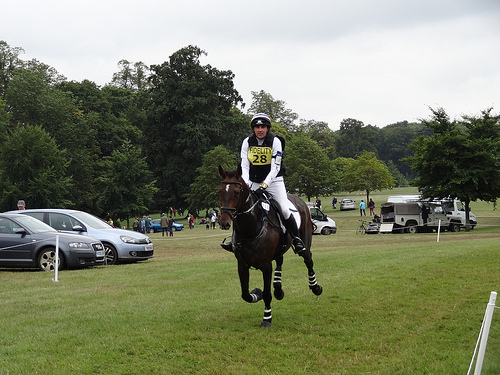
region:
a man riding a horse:
[197, 92, 342, 330]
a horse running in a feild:
[172, 178, 319, 315]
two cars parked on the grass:
[0, 211, 167, 283]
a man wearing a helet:
[214, 102, 302, 194]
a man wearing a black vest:
[232, 91, 287, 204]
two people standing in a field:
[353, 193, 378, 214]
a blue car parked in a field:
[148, 209, 182, 243]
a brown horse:
[186, 161, 342, 323]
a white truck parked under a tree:
[361, 107, 494, 277]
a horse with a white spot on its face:
[207, 160, 246, 246]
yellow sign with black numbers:
[244, 137, 286, 174]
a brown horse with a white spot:
[212, 168, 300, 293]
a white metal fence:
[6, 232, 71, 279]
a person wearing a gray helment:
[249, 110, 279, 141]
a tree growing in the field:
[423, 112, 498, 249]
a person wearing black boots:
[285, 189, 320, 283]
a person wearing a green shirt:
[356, 188, 368, 221]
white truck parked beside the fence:
[380, 194, 471, 255]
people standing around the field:
[134, 203, 194, 248]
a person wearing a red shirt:
[169, 202, 180, 220]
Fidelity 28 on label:
[235, 137, 290, 175]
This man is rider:
[172, 93, 344, 341]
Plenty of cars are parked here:
[11, 167, 478, 284]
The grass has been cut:
[42, 203, 490, 360]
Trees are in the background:
[8, 26, 418, 200]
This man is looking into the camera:
[232, 99, 323, 263]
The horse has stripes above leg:
[192, 205, 357, 345]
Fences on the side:
[36, 220, 491, 344]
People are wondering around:
[299, 163, 410, 238]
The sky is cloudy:
[135, 9, 433, 147]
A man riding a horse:
[207, 110, 342, 321]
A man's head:
[231, 112, 282, 139]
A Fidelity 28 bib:
[244, 141, 280, 169]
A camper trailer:
[363, 183, 480, 244]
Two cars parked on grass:
[2, 193, 163, 282]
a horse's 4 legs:
[227, 260, 340, 336]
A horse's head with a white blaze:
[191, 159, 253, 236]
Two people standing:
[356, 194, 377, 220]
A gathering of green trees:
[16, 44, 180, 174]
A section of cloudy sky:
[299, 12, 424, 99]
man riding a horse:
[217, 112, 326, 334]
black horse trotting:
[216, 179, 331, 336]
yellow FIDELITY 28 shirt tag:
[247, 144, 275, 166]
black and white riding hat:
[247, 110, 269, 127]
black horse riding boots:
[282, 211, 307, 254]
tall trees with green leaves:
[405, 101, 496, 206]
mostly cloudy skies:
[227, 3, 492, 91]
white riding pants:
[247, 175, 290, 216]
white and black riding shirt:
[232, 132, 282, 185]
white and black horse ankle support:
[260, 304, 275, 322]